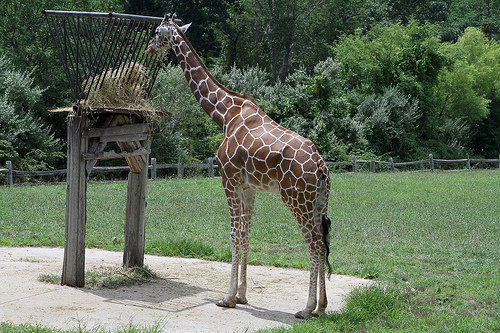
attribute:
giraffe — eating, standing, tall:
[156, 30, 352, 287]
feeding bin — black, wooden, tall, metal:
[49, 5, 167, 111]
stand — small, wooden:
[60, 111, 150, 298]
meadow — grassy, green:
[159, 129, 498, 261]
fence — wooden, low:
[145, 138, 500, 185]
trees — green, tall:
[202, 0, 392, 109]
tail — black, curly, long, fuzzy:
[321, 178, 335, 273]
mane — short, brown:
[178, 30, 264, 102]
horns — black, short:
[162, 10, 178, 24]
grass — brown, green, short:
[329, 175, 496, 261]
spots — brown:
[226, 133, 287, 165]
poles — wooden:
[59, 158, 155, 282]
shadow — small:
[233, 296, 309, 325]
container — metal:
[70, 15, 145, 120]